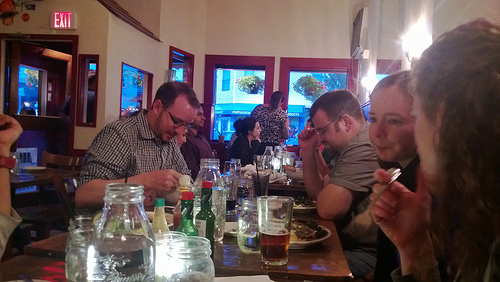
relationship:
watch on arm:
[1, 153, 20, 176] [0, 113, 23, 266]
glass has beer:
[259, 195, 294, 265] [261, 226, 289, 265]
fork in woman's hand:
[345, 167, 403, 239] [370, 163, 431, 246]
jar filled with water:
[238, 197, 262, 255] [238, 217, 263, 254]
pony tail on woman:
[267, 90, 285, 113] [250, 89, 290, 157]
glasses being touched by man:
[314, 118, 345, 136] [298, 88, 381, 278]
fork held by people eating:
[345, 167, 403, 239] [365, 16, 499, 281]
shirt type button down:
[75, 107, 194, 217] [156, 139, 167, 172]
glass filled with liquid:
[259, 195, 294, 265] [261, 226, 289, 265]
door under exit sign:
[2, 33, 77, 204] [50, 11, 78, 30]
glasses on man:
[314, 118, 345, 136] [298, 88, 381, 278]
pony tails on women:
[227, 91, 285, 137] [230, 91, 290, 164]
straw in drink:
[59, 192, 86, 234] [65, 216, 96, 281]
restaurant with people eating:
[1, 0, 500, 281] [4, 19, 500, 281]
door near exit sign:
[2, 33, 77, 204] [50, 11, 78, 30]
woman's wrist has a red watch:
[1, 141, 16, 180] [1, 153, 20, 176]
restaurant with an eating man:
[1, 0, 500, 281] [298, 88, 381, 278]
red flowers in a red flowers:
[293, 75, 329, 102] [293, 75, 328, 101]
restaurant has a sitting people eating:
[1, 0, 500, 281] [365, 16, 499, 281]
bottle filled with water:
[88, 183, 154, 281] [87, 234, 156, 281]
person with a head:
[73, 79, 200, 221] [152, 80, 198, 143]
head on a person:
[152, 80, 198, 143] [73, 79, 200, 221]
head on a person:
[372, 72, 418, 163] [370, 70, 420, 280]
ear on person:
[153, 95, 161, 116] [73, 79, 200, 221]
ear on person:
[341, 114, 353, 133] [298, 88, 381, 278]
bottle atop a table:
[196, 179, 216, 260] [0, 161, 353, 281]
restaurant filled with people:
[1, 0, 500, 281] [0, 19, 498, 281]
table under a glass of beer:
[0, 161, 353, 281] [259, 195, 294, 265]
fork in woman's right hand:
[345, 167, 403, 239] [370, 163, 431, 246]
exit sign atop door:
[50, 11, 78, 30] [2, 33, 77, 204]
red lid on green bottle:
[201, 180, 213, 189] [196, 179, 216, 260]